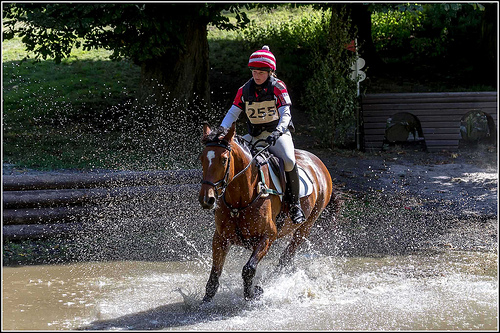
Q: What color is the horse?
A: Brown.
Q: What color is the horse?
A: Brown.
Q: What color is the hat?
A: Red and white.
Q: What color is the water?
A: Brown.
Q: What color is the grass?
A: Green.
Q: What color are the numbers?
A: Black.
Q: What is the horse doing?
A: Running.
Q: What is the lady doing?
A: Riding the horse.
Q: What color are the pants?
A: White.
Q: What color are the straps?
A: Black.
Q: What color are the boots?
A: Black.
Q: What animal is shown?
A: Horse.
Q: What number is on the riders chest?
A: Two fifty five.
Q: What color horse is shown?
A: Brown.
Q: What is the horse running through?
A: Water.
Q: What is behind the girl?
A: Trees on a hill.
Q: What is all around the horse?
A: Water splash.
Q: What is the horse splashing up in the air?
A: Water.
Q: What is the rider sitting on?
A: Saddle.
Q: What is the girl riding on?
A: A horse.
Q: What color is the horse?
A: Brown.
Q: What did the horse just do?
A: Jumped a wall.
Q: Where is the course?
A: In the country.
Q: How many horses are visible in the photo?
A: One.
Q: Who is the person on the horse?
A: Jockey.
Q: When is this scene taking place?
A: Daytime.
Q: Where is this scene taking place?
A: Field and water.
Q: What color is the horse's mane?
A: Black.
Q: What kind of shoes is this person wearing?
A: Riding boots.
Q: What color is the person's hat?
A: Red and grey.